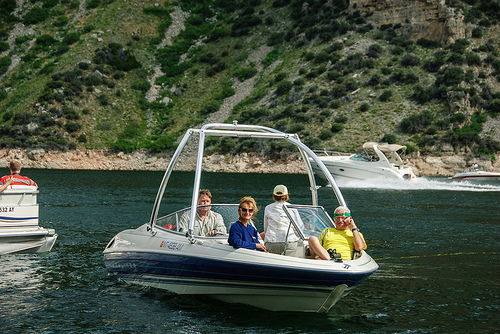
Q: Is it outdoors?
A: Yes, it is outdoors.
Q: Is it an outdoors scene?
A: Yes, it is outdoors.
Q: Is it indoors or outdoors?
A: It is outdoors.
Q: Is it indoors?
A: No, it is outdoors.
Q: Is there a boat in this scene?
A: Yes, there is a boat.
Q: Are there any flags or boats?
A: Yes, there is a boat.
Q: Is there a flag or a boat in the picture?
A: Yes, there is a boat.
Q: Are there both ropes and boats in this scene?
A: No, there is a boat but no ropes.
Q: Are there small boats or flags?
A: Yes, there is a small boat.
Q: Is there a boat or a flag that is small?
A: Yes, the boat is small.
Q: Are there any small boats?
A: Yes, there is a small boat.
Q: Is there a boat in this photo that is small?
A: Yes, there is a boat that is small.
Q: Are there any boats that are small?
A: Yes, there is a boat that is small.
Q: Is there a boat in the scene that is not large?
A: Yes, there is a small boat.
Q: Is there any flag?
A: No, there are no flags.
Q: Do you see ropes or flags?
A: No, there are no flags or ropes.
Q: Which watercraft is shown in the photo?
A: The watercraft is a boat.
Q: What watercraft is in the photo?
A: The watercraft is a boat.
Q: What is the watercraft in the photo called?
A: The watercraft is a boat.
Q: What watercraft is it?
A: The watercraft is a boat.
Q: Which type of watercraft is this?
A: This is a boat.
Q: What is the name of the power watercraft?
A: The watercraft is a boat.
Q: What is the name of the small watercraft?
A: The watercraft is a boat.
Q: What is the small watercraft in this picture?
A: The watercraft is a boat.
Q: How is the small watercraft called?
A: The watercraft is a boat.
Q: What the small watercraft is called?
A: The watercraft is a boat.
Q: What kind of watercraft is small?
A: The watercraft is a boat.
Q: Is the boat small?
A: Yes, the boat is small.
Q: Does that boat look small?
A: Yes, the boat is small.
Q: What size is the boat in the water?
A: The boat is small.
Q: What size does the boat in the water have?
A: The boat has small size.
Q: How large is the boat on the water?
A: The boat is small.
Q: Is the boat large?
A: No, the boat is small.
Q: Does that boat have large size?
A: No, the boat is small.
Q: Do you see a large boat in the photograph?
A: No, there is a boat but it is small.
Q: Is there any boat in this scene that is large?
A: No, there is a boat but it is small.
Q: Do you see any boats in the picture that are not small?
A: No, there is a boat but it is small.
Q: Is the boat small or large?
A: The boat is small.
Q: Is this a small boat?
A: Yes, this is a small boat.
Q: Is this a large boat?
A: No, this is a small boat.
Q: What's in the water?
A: The boat is in the water.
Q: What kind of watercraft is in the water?
A: The watercraft is a boat.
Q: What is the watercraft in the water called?
A: The watercraft is a boat.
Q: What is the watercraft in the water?
A: The watercraft is a boat.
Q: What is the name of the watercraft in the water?
A: The watercraft is a boat.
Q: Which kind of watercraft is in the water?
A: The watercraft is a boat.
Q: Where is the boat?
A: The boat is in the water.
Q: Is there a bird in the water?
A: No, there is a boat in the water.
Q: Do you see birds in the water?
A: No, there is a boat in the water.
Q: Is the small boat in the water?
A: Yes, the boat is in the water.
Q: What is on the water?
A: The boat is on the water.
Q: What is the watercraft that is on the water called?
A: The watercraft is a boat.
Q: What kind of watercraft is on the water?
A: The watercraft is a boat.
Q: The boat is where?
A: The boat is on the water.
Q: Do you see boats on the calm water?
A: Yes, there is a boat on the water.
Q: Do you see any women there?
A: Yes, there is a woman.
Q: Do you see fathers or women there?
A: Yes, there is a woman.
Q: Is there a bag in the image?
A: No, there are no bags.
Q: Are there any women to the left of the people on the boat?
A: Yes, there is a woman to the left of the people.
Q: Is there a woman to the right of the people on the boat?
A: No, the woman is to the left of the people.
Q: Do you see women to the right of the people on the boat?
A: No, the woman is to the left of the people.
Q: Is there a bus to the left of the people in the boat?
A: No, there is a woman to the left of the people.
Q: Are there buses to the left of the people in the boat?
A: No, there is a woman to the left of the people.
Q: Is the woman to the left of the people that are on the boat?
A: Yes, the woman is to the left of the people.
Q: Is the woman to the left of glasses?
A: No, the woman is to the left of the people.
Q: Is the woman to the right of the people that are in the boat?
A: No, the woman is to the left of the people.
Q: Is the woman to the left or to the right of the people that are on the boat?
A: The woman is to the left of the people.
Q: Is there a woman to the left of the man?
A: Yes, there is a woman to the left of the man.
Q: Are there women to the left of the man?
A: Yes, there is a woman to the left of the man.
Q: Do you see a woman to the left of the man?
A: Yes, there is a woman to the left of the man.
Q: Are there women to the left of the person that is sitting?
A: Yes, there is a woman to the left of the man.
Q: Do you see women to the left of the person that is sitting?
A: Yes, there is a woman to the left of the man.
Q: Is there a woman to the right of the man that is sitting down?
A: No, the woman is to the left of the man.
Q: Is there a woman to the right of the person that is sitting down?
A: No, the woman is to the left of the man.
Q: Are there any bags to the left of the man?
A: No, there is a woman to the left of the man.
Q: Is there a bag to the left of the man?
A: No, there is a woman to the left of the man.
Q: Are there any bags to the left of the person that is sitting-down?
A: No, there is a woman to the left of the man.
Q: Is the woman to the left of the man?
A: Yes, the woman is to the left of the man.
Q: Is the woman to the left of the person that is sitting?
A: Yes, the woman is to the left of the man.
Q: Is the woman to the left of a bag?
A: No, the woman is to the left of the man.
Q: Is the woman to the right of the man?
A: No, the woman is to the left of the man.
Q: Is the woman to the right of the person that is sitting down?
A: No, the woman is to the left of the man.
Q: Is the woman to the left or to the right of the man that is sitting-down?
A: The woman is to the left of the man.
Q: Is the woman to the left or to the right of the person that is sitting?
A: The woman is to the left of the man.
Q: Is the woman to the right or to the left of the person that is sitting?
A: The woman is to the left of the man.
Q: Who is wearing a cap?
A: The woman is wearing a cap.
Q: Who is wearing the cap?
A: The woman is wearing a cap.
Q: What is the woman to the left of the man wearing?
A: The woman is wearing a cap.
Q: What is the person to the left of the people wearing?
A: The woman is wearing a cap.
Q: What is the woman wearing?
A: The woman is wearing a cap.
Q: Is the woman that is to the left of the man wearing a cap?
A: Yes, the woman is wearing a cap.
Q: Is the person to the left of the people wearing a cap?
A: Yes, the woman is wearing a cap.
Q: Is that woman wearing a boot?
A: No, the woman is wearing a cap.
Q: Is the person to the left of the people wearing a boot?
A: No, the woman is wearing a cap.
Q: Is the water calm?
A: Yes, the water is calm.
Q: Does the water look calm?
A: Yes, the water is calm.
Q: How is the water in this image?
A: The water is calm.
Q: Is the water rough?
A: No, the water is calm.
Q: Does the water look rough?
A: No, the water is calm.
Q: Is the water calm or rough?
A: The water is calm.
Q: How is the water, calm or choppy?
A: The water is calm.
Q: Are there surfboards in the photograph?
A: No, there are no surfboards.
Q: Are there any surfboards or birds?
A: No, there are no surfboards or birds.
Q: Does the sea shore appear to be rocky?
A: Yes, the sea shore is rocky.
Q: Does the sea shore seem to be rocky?
A: Yes, the sea shore is rocky.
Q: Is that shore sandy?
A: No, the shore is rocky.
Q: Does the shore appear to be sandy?
A: No, the shore is rocky.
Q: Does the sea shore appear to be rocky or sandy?
A: The sea shore is rocky.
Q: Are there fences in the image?
A: No, there are no fences.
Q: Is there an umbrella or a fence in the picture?
A: No, there are no fences or umbrellas.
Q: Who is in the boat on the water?
A: The people are in the boat.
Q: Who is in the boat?
A: The people are in the boat.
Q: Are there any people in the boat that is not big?
A: Yes, there are people in the boat.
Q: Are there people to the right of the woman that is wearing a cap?
A: Yes, there are people to the right of the woman.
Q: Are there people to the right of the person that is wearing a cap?
A: Yes, there are people to the right of the woman.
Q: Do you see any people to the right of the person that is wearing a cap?
A: Yes, there are people to the right of the woman.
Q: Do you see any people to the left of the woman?
A: No, the people are to the right of the woman.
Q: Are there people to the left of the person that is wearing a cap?
A: No, the people are to the right of the woman.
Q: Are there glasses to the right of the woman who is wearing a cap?
A: No, there are people to the right of the woman.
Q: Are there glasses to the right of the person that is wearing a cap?
A: No, there are people to the right of the woman.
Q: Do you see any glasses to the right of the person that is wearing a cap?
A: No, there are people to the right of the woman.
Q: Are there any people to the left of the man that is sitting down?
A: Yes, there are people to the left of the man.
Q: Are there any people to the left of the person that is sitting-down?
A: Yes, there are people to the left of the man.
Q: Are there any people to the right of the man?
A: No, the people are to the left of the man.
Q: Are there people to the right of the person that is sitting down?
A: No, the people are to the left of the man.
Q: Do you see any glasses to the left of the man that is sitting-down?
A: No, there are people to the left of the man.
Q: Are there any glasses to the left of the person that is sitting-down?
A: No, there are people to the left of the man.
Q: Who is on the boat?
A: The people are on the boat.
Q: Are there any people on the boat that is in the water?
A: Yes, there are people on the boat.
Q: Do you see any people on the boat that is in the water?
A: Yes, there are people on the boat.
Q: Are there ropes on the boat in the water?
A: No, there are people on the boat.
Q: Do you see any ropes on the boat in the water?
A: No, there are people on the boat.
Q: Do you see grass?
A: Yes, there is grass.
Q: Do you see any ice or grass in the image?
A: Yes, there is grass.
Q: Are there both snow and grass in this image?
A: No, there is grass but no snow.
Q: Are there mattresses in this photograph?
A: No, there are no mattresses.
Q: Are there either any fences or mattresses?
A: No, there are no mattresses or fences.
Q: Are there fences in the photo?
A: No, there are no fences.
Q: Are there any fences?
A: No, there are no fences.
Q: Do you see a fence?
A: No, there are no fences.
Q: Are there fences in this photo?
A: No, there are no fences.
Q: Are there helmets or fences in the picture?
A: No, there are no fences or helmets.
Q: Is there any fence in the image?
A: No, there are no fences.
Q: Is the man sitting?
A: Yes, the man is sitting.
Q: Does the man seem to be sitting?
A: Yes, the man is sitting.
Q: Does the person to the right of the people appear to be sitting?
A: Yes, the man is sitting.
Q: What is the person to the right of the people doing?
A: The man is sitting.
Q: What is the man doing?
A: The man is sitting.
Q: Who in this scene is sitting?
A: The man is sitting.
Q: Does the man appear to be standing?
A: No, the man is sitting.